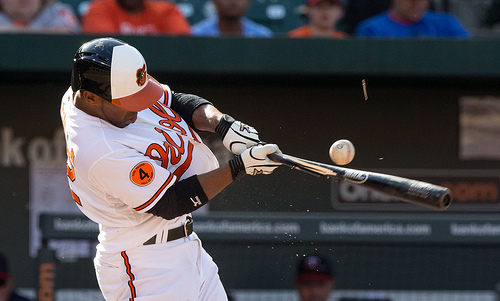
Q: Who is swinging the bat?
A: The man.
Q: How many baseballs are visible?
A: One.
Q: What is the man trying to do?
A: Hit the ball.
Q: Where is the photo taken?
A: Baseball Field.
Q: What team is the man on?
A: Baltimore Orioles.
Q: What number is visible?
A: Four.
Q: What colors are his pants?
A: Orange and White.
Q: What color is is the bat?
A: Black.